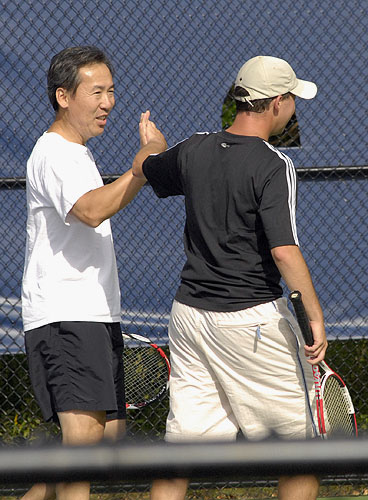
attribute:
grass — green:
[1, 408, 71, 461]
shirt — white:
[24, 132, 133, 330]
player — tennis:
[144, 37, 335, 402]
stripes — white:
[281, 140, 300, 244]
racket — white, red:
[289, 289, 358, 442]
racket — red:
[119, 330, 169, 410]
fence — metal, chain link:
[2, 0, 367, 493]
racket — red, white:
[118, 333, 163, 415]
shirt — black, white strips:
[167, 120, 302, 314]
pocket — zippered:
[218, 321, 257, 333]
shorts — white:
[145, 289, 324, 476]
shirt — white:
[21, 130, 122, 331]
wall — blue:
[3, 1, 366, 361]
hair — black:
[47, 44, 115, 112]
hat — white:
[233, 54, 318, 93]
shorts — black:
[22, 319, 128, 425]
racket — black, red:
[278, 274, 365, 445]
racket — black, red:
[110, 325, 175, 419]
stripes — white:
[260, 138, 305, 245]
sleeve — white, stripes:
[257, 157, 306, 248]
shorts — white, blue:
[158, 297, 337, 444]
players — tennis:
[148, 53, 355, 496]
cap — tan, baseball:
[232, 53, 317, 105]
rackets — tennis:
[118, 289, 359, 437]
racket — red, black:
[295, 292, 363, 443]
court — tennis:
[2, 282, 349, 484]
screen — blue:
[4, 27, 356, 336]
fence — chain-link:
[3, 5, 352, 443]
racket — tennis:
[110, 297, 174, 416]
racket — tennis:
[289, 286, 355, 457]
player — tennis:
[140, 54, 326, 494]